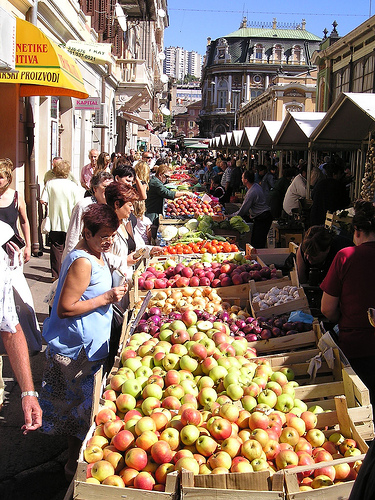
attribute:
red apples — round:
[155, 268, 224, 279]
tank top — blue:
[38, 247, 121, 365]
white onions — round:
[252, 283, 300, 307]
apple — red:
[114, 333, 317, 472]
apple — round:
[187, 365, 252, 429]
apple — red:
[180, 264, 197, 276]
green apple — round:
[120, 355, 144, 374]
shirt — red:
[319, 241, 374, 313]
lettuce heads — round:
[184, 215, 247, 236]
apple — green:
[134, 362, 155, 383]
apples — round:
[133, 251, 295, 289]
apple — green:
[121, 377, 145, 399]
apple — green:
[258, 389, 275, 407]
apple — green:
[279, 394, 293, 411]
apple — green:
[159, 350, 178, 370]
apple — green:
[210, 418, 230, 438]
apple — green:
[274, 450, 297, 470]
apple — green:
[112, 430, 137, 450]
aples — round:
[150, 251, 251, 267]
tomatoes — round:
[223, 244, 229, 253]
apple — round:
[206, 247, 238, 263]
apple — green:
[161, 352, 182, 370]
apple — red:
[197, 274, 213, 287]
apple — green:
[155, 425, 183, 450]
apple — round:
[120, 347, 218, 419]